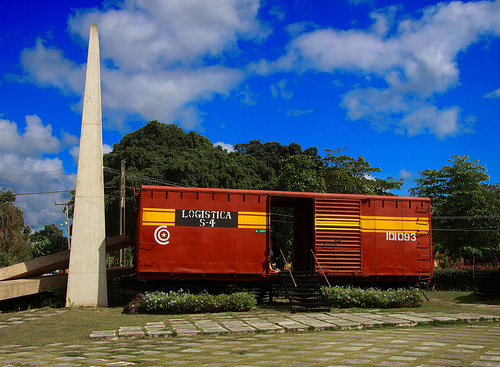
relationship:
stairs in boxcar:
[279, 249, 332, 313] [128, 179, 438, 305]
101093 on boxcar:
[384, 231, 416, 242] [132, 180, 433, 280]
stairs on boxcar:
[274, 250, 334, 312] [132, 185, 434, 285]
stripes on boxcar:
[142, 204, 431, 233] [132, 185, 434, 285]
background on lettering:
[364, 230, 428, 270] [384, 229, 416, 241]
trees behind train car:
[103, 118, 490, 198] [129, 172, 447, 313]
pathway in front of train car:
[90, 310, 495, 336] [129, 180, 441, 293]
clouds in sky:
[0, 0, 500, 233] [1, 2, 499, 241]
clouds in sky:
[285, 17, 483, 99] [1, 2, 499, 241]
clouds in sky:
[0, 0, 500, 233] [9, 6, 495, 134]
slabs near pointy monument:
[1, 250, 77, 300] [62, 22, 108, 312]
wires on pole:
[103, 164, 188, 196] [118, 153, 128, 268]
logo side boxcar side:
[174, 206, 239, 226] [138, 182, 435, 277]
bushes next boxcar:
[138, 285, 258, 314] [135, 181, 435, 294]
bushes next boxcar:
[317, 281, 422, 306] [135, 181, 435, 294]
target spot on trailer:
[152, 222, 174, 246] [127, 173, 440, 303]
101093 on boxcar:
[380, 225, 420, 244] [132, 185, 434, 285]